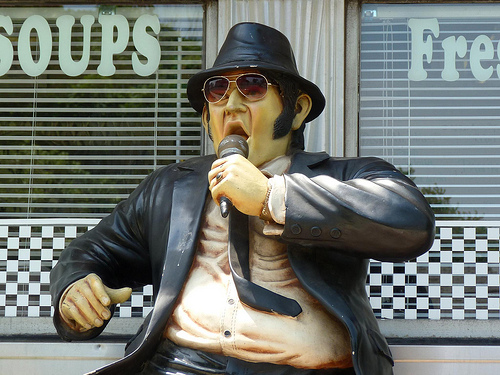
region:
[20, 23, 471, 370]
Picture is taken outside.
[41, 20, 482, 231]
It is daytime.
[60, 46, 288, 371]
A statute is outside.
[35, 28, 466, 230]
The statute is in front of a restaurant.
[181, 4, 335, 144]
The statute has a black had.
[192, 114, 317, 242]
The statute is holding a microphone.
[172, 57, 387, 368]
The statue looks like a blues brother.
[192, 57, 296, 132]
The statue is wearing sun glasses.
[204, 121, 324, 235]
The statute's hand is holding a microphone.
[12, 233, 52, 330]
The wall of the restaurant has black and white tiles.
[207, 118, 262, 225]
fake grey microphone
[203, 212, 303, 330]
a long black tie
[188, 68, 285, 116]
dark sunglasses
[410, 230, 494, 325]
checker board print on building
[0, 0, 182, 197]
window with soup logo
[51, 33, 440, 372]
statue with microphone and glasses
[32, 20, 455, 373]
blues brothers statue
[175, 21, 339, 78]
dark blue hat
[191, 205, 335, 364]
white shirt with black buttons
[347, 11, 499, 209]
window with white blinds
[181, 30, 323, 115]
The statue is wearing a black hat.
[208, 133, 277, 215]
The statue has a mic in hand.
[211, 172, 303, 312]
The tie is black.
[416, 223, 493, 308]
The building is black and white checkered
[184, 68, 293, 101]
The statue has on glasses.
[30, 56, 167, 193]
The blinds are in the window.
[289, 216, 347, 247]
The jacket has 3 buttons on the sleeve.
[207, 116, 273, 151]
The mouth is open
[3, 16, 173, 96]
The window has word soups on it.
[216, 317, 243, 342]
The button is black.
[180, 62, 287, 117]
Sunglasses propped on a plastic figure's face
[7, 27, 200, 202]
Blinds in a window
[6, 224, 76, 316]
Black and white checked pattern under a window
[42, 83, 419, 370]
A plastic figure wearing a suit and tie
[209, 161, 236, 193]
A ring on a plastic figure's finger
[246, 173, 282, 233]
A watch on a plastic figure's wrist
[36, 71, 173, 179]
Trees reflected in a window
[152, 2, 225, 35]
Blue sky reflected in a window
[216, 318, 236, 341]
Black button on a plastic figure's shirt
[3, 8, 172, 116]
The word SOUPS painted on the window of a restaurant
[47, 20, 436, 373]
statue of a singer in front of diner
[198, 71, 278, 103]
sunglasses on statue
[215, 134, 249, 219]
statue is holding a microphone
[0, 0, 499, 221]
diner had two windows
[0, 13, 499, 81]
white lettering on windows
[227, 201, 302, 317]
statue has black tie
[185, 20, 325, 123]
statue has black hat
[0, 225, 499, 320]
black and white tiles under windows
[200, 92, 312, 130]
statue has two ears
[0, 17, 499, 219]
white blinds behind windows